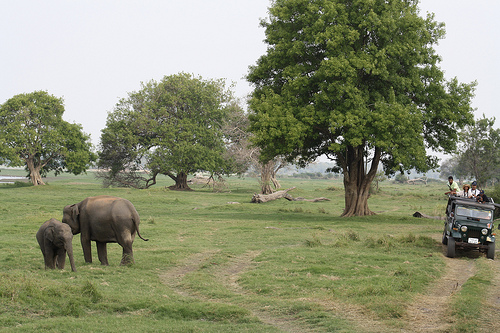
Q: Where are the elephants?
A: Grass.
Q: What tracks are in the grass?
A: Vehicle.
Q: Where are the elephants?
A: Together.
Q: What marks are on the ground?
A: Rut.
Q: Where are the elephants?
A: Field.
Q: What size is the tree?
A: Large.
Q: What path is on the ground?
A: Dirt.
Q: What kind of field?
A: Grass.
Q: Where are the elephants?
A: Field.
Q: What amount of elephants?
A: Two.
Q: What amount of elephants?
A: Two.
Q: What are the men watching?
A: Elephants.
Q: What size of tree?
A: Large.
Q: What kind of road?
A: Dirt.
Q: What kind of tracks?
A: Tire.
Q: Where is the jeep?
A: On the right.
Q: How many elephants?
A: Two.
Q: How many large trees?
A: Three.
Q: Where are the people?
A: In vehicle.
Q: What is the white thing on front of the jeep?
A: A license plate.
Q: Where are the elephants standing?
A: Grass.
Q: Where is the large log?
A: Beside the tree.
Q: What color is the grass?
A: Green.